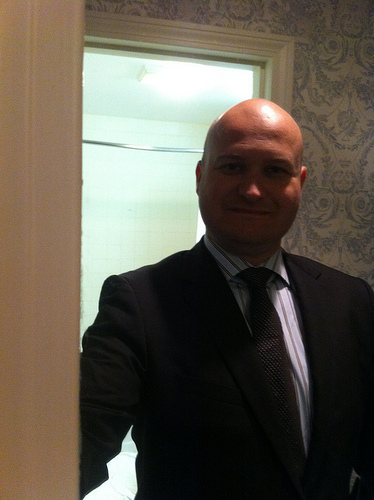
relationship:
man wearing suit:
[79, 95, 373, 500] [79, 237, 374, 499]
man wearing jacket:
[79, 95, 373, 500] [79, 237, 374, 499]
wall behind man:
[86, 0, 373, 292] [79, 95, 373, 500]